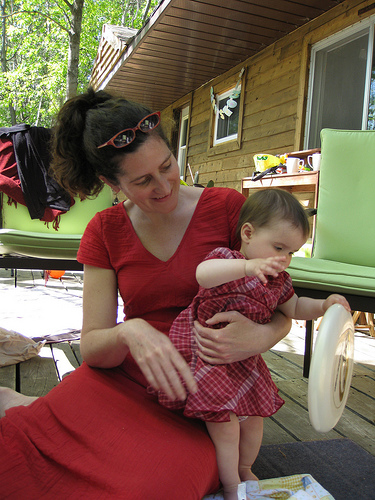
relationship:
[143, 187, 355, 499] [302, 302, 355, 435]
baby holds frisbee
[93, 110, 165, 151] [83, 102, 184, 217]
red glasses are on top of woman's head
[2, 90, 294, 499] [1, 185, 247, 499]
woman wearing red dress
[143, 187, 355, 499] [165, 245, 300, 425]
baby wearing red plaid dress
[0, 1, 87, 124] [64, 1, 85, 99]
tree has trunk.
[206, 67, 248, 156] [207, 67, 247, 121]
window has decorations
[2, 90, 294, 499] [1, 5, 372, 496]
person sitting outside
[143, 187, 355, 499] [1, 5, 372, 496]
person sitting outside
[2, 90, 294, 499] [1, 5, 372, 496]
woman sits outside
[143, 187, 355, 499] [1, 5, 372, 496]
baby stands outside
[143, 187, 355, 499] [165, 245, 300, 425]
baby wears red plaid dress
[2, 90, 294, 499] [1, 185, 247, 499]
woman wears red dress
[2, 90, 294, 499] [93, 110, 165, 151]
woman wearing red glasses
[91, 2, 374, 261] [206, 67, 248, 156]
building has a window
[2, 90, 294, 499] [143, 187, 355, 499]
woman holds baby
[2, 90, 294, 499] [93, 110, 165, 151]
woman wears red glasses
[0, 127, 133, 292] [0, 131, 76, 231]
back chair sits under baby blanket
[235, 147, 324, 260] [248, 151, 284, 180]
table sits under bowl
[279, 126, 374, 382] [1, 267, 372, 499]
chair on deck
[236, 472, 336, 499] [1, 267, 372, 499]
blanket on deck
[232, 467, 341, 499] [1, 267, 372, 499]
blanket on floor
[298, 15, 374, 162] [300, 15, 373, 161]
window has a window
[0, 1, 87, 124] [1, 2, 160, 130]
tree has leaves